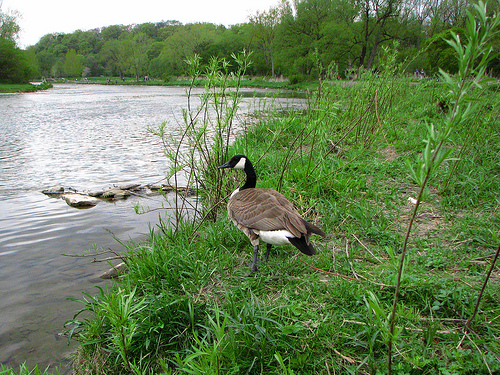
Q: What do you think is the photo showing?
A: It is showing a river.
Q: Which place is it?
A: It is a river.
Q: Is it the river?
A: Yes, it is the river.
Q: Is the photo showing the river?
A: Yes, it is showing the river.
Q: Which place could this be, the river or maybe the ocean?
A: It is the river.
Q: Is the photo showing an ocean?
A: No, the picture is showing a river.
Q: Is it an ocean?
A: No, it is a river.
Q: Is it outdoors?
A: Yes, it is outdoors.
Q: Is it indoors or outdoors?
A: It is outdoors.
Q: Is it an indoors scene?
A: No, it is outdoors.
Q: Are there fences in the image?
A: No, there are no fences.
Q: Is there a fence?
A: No, there are no fences.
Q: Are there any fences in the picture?
A: No, there are no fences.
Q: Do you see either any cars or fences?
A: No, there are no fences or cars.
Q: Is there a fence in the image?
A: No, there are no fences.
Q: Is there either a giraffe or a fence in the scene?
A: No, there are no fences or giraffes.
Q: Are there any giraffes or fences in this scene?
A: No, there are no fences or giraffes.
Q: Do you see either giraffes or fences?
A: No, there are no fences or giraffes.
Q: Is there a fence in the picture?
A: No, there are no fences.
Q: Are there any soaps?
A: No, there are no soaps.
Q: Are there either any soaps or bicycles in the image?
A: No, there are no soaps or bicycles.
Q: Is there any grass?
A: Yes, there is grass.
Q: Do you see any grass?
A: Yes, there is grass.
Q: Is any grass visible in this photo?
A: Yes, there is grass.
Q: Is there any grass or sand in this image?
A: Yes, there is grass.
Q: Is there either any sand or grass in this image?
A: Yes, there is grass.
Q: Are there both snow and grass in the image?
A: No, there is grass but no snow.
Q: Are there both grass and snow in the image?
A: No, there is grass but no snow.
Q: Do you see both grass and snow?
A: No, there is grass but no snow.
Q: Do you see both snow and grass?
A: No, there is grass but no snow.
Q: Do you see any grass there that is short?
A: Yes, there is short grass.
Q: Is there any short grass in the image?
A: Yes, there is short grass.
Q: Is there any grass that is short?
A: Yes, there is grass that is short.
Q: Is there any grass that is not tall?
A: Yes, there is short grass.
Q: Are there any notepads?
A: No, there are no notepads.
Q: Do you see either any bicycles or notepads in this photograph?
A: No, there are no notepads or bicycles.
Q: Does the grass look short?
A: Yes, the grass is short.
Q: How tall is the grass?
A: The grass is short.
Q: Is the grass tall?
A: No, the grass is short.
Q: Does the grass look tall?
A: No, the grass is short.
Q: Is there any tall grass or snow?
A: No, there is grass but it is short.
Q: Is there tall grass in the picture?
A: No, there is grass but it is short.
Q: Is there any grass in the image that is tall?
A: No, there is grass but it is short.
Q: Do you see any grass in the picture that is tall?
A: No, there is grass but it is short.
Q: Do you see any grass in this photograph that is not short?
A: No, there is grass but it is short.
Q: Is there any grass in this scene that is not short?
A: No, there is grass but it is short.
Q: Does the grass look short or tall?
A: The grass is short.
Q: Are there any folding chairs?
A: No, there are no folding chairs.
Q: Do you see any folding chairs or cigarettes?
A: No, there are no folding chairs or cigarettes.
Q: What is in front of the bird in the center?
A: The plant is in front of the bird.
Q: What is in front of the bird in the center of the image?
A: The plant is in front of the bird.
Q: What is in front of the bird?
A: The plant is in front of the bird.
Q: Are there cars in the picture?
A: No, there are no cars.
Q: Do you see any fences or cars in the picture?
A: No, there are no cars or fences.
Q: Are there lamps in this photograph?
A: No, there are no lamps.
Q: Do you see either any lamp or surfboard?
A: No, there are no lamps or surfboards.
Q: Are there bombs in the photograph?
A: No, there are no bombs.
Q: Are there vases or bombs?
A: No, there are no bombs or vases.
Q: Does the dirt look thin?
A: Yes, the dirt is thin.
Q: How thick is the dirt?
A: The dirt is thin.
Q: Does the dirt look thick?
A: No, the dirt is thin.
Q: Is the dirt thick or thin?
A: The dirt is thin.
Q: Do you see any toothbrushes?
A: No, there are no toothbrushes.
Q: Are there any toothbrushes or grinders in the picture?
A: No, there are no toothbrushes or grinders.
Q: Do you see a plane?
A: No, there are no airplanes.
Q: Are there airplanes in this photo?
A: No, there are no airplanes.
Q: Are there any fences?
A: No, there are no fences.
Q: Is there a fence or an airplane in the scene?
A: No, there are no fences or airplanes.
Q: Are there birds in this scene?
A: Yes, there is a bird.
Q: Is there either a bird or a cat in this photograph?
A: Yes, there is a bird.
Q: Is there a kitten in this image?
A: No, there are no kittens.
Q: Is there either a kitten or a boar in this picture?
A: No, there are no kittens or boars.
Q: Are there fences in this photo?
A: No, there are no fences.